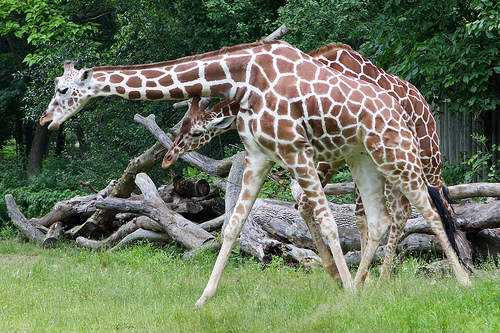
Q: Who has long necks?
A: The giraffe.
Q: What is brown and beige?
A: Giraffe.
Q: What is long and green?
A: The grass.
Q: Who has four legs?
A: One giraffe.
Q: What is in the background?
A: Trees.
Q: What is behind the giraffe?
A: Logs.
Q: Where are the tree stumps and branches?
A: Behind the giraffes.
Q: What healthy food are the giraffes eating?
A: Green grass.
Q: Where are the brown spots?
A: On the giraffe's body.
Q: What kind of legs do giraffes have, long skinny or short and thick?
A: Long skinny legs.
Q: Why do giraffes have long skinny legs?
A: To help them reach tree leaves.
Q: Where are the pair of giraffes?
A: In a field.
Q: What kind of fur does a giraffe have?
A: Short brown and white.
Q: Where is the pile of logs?
A: Behind the giraffes.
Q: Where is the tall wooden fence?
A: Behind and to the right of the giraffes.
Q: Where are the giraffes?
A: On the ground.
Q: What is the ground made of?
A: Grass.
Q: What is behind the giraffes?
A: Logs.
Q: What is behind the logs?
A: A row of trees.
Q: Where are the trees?
A: Behind the logs.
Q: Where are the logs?
A: Behind the giraffes.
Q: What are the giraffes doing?
A: Standing.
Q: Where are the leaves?
A: On the trees.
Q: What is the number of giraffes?
A: Two.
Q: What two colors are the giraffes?
A: White and brown.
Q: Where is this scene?
A: A zoo or refuge.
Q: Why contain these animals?
A: To control and view them.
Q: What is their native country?
A: Africa.